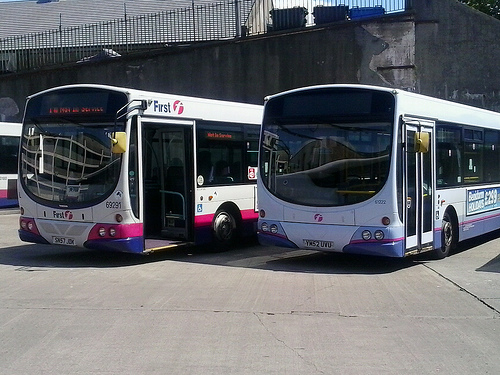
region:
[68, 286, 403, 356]
The ground is made of concrete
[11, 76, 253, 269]
The bus is sitting on the ground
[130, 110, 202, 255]
The door to the bus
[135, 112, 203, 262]
The bus door is open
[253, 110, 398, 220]
The front window of the bus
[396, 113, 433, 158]
The rear view window of the bus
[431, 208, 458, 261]
The front tire of the bus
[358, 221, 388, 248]
The head light of the bus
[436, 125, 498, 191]
The side windows of the bus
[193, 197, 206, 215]
The handicap sticker on the bus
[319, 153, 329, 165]
window of a bus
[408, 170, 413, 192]
part of a door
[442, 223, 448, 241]
part of a wheel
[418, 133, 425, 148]
mirror of a bus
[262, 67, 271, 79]
part of a wall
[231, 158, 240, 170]
part of a window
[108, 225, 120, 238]
part of a light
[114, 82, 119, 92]
top of a bus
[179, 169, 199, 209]
part of a door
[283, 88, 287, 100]
top of a bus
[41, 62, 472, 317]
two buses on road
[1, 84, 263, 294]
red and white bus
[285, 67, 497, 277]
blue and white bus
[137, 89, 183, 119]
red and white logo on side of bus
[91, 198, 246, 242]
red stripe on bus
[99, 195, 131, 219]
black numbers on front of bus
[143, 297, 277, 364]
sidewalk is light grey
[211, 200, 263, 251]
black wheels on bus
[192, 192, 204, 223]
blue handicap sign on bus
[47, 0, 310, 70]
black railing over bus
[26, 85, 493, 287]
two buses in the bus stand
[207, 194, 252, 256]
wheel of the bus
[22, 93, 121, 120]
display board of the bus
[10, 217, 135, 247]
headlights with side indicator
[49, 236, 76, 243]
number plate of the bus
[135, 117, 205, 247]
main door of the bus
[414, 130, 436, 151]
side mirror of the bus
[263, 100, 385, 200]
front glass with wiper of the bus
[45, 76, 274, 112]
top of the bus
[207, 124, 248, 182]
windows of the bus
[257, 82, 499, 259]
white and blue bus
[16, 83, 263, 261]
pink blue and white bus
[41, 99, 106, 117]
electronic destination sign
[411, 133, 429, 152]
side mirror on bus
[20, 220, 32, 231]
head lights on bus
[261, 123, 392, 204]
wind shield on bus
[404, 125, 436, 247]
white doors on bus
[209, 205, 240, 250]
rubber tire on bus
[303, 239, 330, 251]
license plate on bus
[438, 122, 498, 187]
window on side of bus